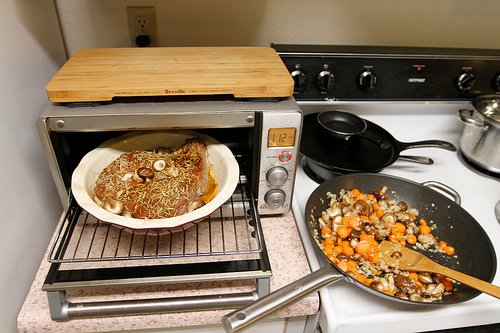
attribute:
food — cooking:
[327, 194, 450, 293]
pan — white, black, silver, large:
[302, 168, 497, 316]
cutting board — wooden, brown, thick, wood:
[45, 45, 298, 105]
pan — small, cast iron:
[299, 105, 463, 177]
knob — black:
[354, 70, 381, 90]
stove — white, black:
[271, 38, 499, 325]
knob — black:
[311, 66, 328, 94]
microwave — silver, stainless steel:
[29, 104, 304, 247]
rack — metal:
[50, 177, 264, 264]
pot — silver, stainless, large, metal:
[457, 90, 500, 180]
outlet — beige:
[117, 2, 173, 43]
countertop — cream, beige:
[6, 214, 317, 332]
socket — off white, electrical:
[125, 3, 161, 50]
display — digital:
[267, 126, 297, 149]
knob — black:
[457, 71, 481, 93]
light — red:
[415, 66, 424, 72]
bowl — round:
[65, 134, 250, 242]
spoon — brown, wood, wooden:
[374, 237, 499, 309]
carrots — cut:
[341, 235, 384, 273]